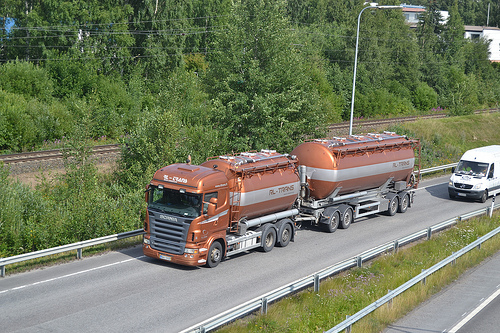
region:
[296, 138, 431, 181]
Tanker is copper and silver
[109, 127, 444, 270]
Tractor pulling two tankers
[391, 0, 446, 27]
House nestled in trees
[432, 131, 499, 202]
White van next to tanker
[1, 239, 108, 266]
Guardrail on side of freeway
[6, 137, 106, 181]
Tree tracks on embankment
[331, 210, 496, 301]
White flowers growing in grass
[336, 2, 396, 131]
Street light on side of freeway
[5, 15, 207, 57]
Telephone lines above tracks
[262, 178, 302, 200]
Brown writing on tanker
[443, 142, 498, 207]
white van driving along the road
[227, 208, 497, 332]
strip of grass between the two sides of the road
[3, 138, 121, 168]
train tracks behind the trees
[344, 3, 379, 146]
tall and skinny light post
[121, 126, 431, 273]
orange truck with two trailers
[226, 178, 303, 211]
silver stripe on the orange paint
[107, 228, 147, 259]
the truck's shadow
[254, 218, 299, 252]
two wheels working side by side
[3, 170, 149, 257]
green shrubbery along the side of the road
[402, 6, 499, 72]
building peaking through the trees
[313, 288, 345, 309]
this is the grass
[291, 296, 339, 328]
the grass is green in color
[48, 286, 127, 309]
this is the road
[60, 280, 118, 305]
the road is clean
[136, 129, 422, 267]
this is a truck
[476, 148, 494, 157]
the car is white in color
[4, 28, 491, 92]
these are several trees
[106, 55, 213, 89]
the leaves are green in color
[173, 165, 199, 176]
the truck is brown in color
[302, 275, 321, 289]
this is a grill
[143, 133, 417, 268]
a large copper colored semi truck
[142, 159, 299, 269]
copper colored tanker truck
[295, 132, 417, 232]
tanker being hauled by a truck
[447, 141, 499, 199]
a white mini van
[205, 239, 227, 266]
left front wheel of a truck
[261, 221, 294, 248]
left rear wheels of a truck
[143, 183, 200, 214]
windshield of a truck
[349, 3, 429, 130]
street lamp on a pole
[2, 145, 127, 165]
small section of train track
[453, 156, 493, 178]
windshield of a minivan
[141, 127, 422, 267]
truck with two rigs attached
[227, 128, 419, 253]
two rigs on the truck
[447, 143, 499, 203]
white truck behind the copper rig truck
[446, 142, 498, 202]
white van on the service road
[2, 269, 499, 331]
service road of the highway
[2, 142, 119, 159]
railroad tracks between the trees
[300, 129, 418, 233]
largest rig on the copper truck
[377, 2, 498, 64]
two buildings behind the trees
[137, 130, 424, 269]
rig truck moving the service road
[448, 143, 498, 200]
white van trying to pass a long rig truck